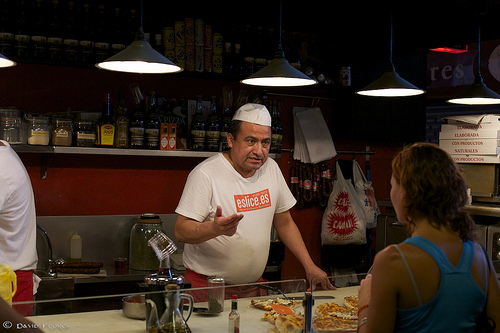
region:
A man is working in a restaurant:
[25, 35, 495, 320]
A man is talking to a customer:
[36, 37, 487, 310]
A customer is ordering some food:
[70, 25, 496, 322]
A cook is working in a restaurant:
[50, 45, 487, 318]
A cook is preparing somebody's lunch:
[60, 48, 496, 319]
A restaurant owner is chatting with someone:
[55, 40, 498, 311]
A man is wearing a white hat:
[168, 70, 308, 176]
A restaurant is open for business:
[33, 35, 498, 325]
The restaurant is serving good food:
[36, 30, 491, 321]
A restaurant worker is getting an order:
[45, 45, 495, 322]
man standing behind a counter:
[44, 98, 359, 330]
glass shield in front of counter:
[0, 271, 369, 331]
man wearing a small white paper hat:
[227, 101, 272, 170]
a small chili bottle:
[226, 295, 242, 332]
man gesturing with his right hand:
[206, 202, 245, 235]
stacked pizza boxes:
[438, 113, 499, 165]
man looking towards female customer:
[220, 103, 478, 260]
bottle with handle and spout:
[142, 282, 193, 332]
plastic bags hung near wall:
[321, 154, 382, 246]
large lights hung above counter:
[0, 30, 499, 332]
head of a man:
[207, 98, 296, 178]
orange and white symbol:
[223, 177, 283, 224]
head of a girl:
[353, 123, 483, 260]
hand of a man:
[204, 200, 249, 247]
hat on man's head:
[231, 95, 283, 131]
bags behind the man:
[299, 163, 374, 259]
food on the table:
[257, 285, 303, 332]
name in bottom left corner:
[3, 318, 95, 332]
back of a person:
[0, 110, 77, 297]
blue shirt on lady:
[378, 216, 493, 325]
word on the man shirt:
[228, 190, 280, 212]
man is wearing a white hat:
[245, 109, 266, 119]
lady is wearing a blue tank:
[435, 287, 461, 314]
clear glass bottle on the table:
[168, 288, 187, 331]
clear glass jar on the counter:
[137, 227, 152, 268]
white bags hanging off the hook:
[335, 188, 369, 226]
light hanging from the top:
[107, 37, 160, 77]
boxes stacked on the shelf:
[459, 114, 475, 161]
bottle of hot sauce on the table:
[227, 295, 235, 332]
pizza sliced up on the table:
[318, 300, 345, 326]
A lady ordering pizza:
[384, 139, 497, 326]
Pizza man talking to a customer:
[167, 97, 324, 303]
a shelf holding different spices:
[15, 83, 218, 149]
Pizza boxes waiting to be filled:
[435, 112, 499, 200]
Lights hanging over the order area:
[83, 33, 431, 123]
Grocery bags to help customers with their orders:
[321, 159, 386, 253]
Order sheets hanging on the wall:
[289, 103, 339, 170]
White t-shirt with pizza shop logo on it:
[198, 145, 308, 297]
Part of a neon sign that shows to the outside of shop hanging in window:
[416, 39, 499, 108]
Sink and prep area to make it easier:
[27, 217, 159, 297]